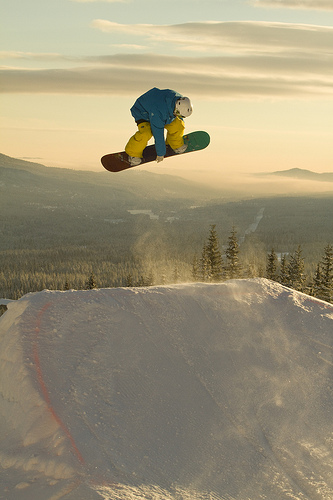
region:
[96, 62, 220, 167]
person is on snowboard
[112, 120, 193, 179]
green and red board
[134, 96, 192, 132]
person has white helmet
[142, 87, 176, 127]
person has blue coat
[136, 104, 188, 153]
person has yellow pants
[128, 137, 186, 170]
person has white shoes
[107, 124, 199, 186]
person is holding board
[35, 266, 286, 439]
white snow on ramp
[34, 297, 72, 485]
orange line painted on ramp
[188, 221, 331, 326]
tall green trees behind ramp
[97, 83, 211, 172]
A snowboarder in mid air.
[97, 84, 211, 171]
A snowboard getting air.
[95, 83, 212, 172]
A snowboarder wearing yellow pants and a blue jacket.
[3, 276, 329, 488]
A snow ramp for snowboarders.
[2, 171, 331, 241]
Mountains in the distance.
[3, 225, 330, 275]
A wooded valley below mountains.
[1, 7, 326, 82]
White clouds in the sky at sunset.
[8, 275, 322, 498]
Snow formed into a ramp for snowboarders.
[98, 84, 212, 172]
A snowboarder riding a red and green snowboard.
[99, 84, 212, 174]
A snowboard wearing a white helmet.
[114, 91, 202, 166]
this is a man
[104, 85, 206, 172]
the boy is on air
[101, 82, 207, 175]
the boy is skating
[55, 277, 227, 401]
the path is hilly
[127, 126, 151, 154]
this is the trousers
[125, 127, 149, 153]
the grousers are yellow in color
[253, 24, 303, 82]
these are the clouds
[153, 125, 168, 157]
this is the hand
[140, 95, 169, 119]
the jacket is blue in color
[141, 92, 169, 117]
the jacket is warm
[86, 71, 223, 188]
A person doing a snowboard trick.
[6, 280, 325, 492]
Snowboard ramp made out of snow.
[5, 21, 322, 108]
Grey clouds in the sky.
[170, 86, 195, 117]
A white safety helmet.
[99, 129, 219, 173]
A red and green snowboard.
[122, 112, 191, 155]
A pair of yellow pants.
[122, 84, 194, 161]
Person wearing a blue jacket.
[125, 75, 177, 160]
A long sleeved jacket.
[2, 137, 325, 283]
Mountains in the distant.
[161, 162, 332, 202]
White hazy clouds between mountains.